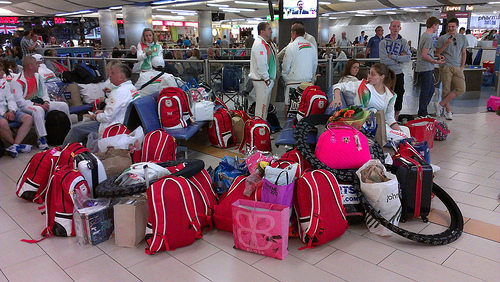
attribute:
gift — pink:
[229, 192, 293, 264]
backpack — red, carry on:
[144, 177, 209, 257]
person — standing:
[439, 15, 471, 127]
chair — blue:
[117, 73, 211, 140]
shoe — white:
[442, 105, 456, 123]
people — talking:
[415, 11, 468, 127]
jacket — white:
[279, 39, 323, 86]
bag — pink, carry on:
[312, 121, 377, 172]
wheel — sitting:
[355, 160, 469, 246]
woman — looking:
[342, 63, 420, 146]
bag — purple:
[258, 157, 293, 207]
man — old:
[98, 57, 141, 128]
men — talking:
[252, 16, 318, 98]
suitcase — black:
[386, 148, 436, 221]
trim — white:
[166, 173, 205, 231]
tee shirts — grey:
[414, 27, 472, 75]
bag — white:
[353, 158, 403, 247]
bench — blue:
[277, 111, 333, 155]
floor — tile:
[443, 110, 498, 213]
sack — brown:
[56, 83, 85, 108]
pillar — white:
[119, 5, 154, 54]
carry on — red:
[157, 82, 197, 136]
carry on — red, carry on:
[241, 114, 277, 149]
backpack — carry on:
[292, 164, 352, 252]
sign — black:
[48, 13, 82, 28]